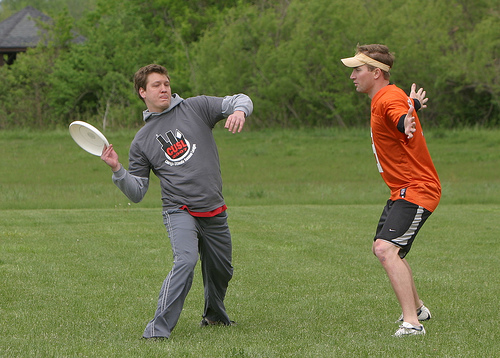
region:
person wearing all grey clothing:
[49, 52, 269, 345]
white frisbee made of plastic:
[63, 114, 113, 164]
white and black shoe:
[387, 321, 429, 342]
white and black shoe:
[392, 302, 432, 324]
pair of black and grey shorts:
[367, 188, 446, 257]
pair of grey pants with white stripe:
[136, 201, 236, 342]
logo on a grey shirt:
[152, 124, 197, 171]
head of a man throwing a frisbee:
[129, 59, 176, 118]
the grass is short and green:
[0, 124, 495, 357]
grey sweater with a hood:
[105, 87, 257, 217]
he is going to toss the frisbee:
[60, 46, 284, 331]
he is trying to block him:
[322, 15, 461, 345]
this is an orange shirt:
[348, 73, 455, 217]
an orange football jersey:
[355, 73, 446, 205]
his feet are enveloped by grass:
[117, 298, 298, 350]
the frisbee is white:
[55, 105, 128, 155]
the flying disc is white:
[55, 98, 126, 157]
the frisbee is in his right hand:
[54, 113, 134, 167]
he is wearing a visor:
[330, 20, 392, 107]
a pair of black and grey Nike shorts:
[351, 177, 443, 246]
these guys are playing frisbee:
[27, 18, 472, 355]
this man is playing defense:
[310, 39, 463, 351]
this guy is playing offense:
[29, 57, 272, 338]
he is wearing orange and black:
[318, 32, 465, 339]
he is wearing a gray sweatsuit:
[35, 56, 268, 356]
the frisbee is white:
[49, 116, 127, 159]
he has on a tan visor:
[329, 44, 401, 94]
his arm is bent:
[191, 86, 291, 133]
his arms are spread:
[326, 39, 442, 158]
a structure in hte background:
[1, 1, 98, 116]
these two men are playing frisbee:
[54, 29, 445, 339]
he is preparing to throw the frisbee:
[67, 49, 278, 197]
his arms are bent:
[30, 69, 275, 204]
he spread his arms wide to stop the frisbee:
[322, 39, 452, 152]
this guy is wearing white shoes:
[374, 299, 435, 354]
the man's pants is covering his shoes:
[112, 286, 265, 352]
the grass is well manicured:
[232, 156, 359, 327]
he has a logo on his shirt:
[141, 125, 209, 170]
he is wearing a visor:
[325, 42, 397, 92]